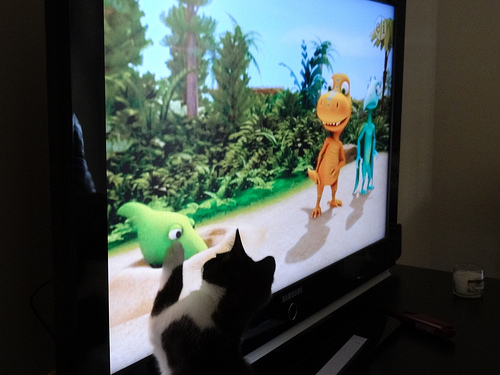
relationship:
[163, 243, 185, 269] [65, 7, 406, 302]
paws on tv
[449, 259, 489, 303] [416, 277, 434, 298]
candle on counter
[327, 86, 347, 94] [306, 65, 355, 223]
eyes on animal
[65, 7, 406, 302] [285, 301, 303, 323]
tv has a power button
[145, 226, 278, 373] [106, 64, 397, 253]
cat watching cartoons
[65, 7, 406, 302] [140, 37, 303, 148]
tv has a screen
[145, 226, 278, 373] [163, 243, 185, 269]
cat has a paw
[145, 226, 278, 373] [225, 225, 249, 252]
cat has an ear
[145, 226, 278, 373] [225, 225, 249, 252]
cat has a ear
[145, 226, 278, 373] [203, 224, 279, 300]
cat has a head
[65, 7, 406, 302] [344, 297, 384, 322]
tv on a stand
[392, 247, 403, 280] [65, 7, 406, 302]
corner of tv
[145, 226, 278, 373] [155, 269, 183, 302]
cat has a leg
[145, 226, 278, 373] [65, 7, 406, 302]
cat in front of tv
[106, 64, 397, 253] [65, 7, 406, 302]
cartoons on tv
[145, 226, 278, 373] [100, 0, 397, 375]
cat blocking screen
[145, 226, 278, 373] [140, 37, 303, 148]
cat pawing at screen